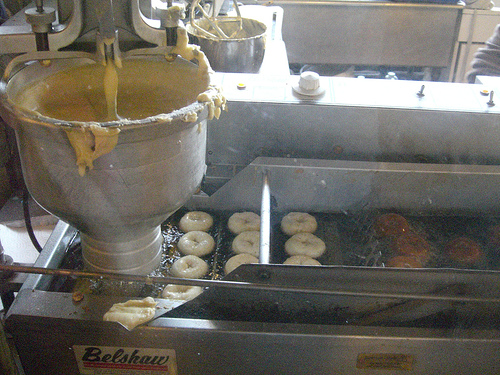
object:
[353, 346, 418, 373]
sticker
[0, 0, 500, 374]
machine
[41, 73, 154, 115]
batter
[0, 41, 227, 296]
mixing bowl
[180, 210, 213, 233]
donut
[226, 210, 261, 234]
donut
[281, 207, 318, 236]
donut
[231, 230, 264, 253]
donut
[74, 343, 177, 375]
name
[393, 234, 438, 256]
donut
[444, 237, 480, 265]
donut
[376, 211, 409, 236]
donut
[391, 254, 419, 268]
donut